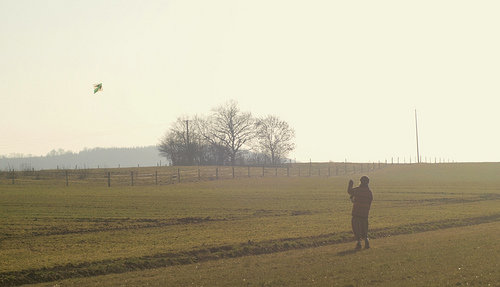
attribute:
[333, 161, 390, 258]
man — flying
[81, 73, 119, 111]
kite — small, overhead, flying, far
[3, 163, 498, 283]
field — muddy, green, covered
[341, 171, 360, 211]
arm — up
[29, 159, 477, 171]
gate — wire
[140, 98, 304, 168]
tree — leafy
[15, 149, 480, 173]
fence — sticks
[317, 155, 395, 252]
person — flying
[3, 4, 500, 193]
skies — cloudy, overlooking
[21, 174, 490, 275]
grass — green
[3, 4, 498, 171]
sky — white, clear